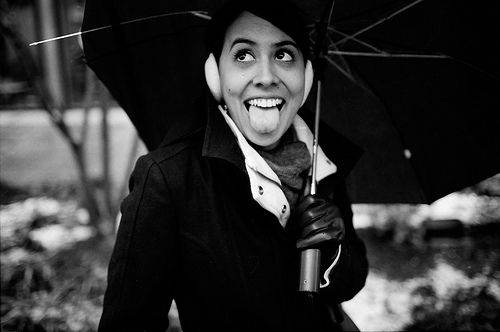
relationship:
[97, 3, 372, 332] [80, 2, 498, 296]
woman holding umbrella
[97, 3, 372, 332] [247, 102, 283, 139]
woman sticking out tongue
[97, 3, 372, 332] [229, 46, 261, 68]
woman has eye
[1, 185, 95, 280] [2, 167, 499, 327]
snow covering ground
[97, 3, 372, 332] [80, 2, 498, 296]
woman carrying umbrella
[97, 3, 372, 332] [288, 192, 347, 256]
woman wearing glove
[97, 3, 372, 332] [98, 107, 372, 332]
woman wearing jacket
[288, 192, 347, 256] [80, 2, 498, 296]
glove holding umbrella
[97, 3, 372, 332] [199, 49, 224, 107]
woman wearing muff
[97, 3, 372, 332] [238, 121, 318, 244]
woman wearing scarf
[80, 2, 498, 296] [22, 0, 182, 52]
umbrella has wire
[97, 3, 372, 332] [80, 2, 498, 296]
woman under umbrella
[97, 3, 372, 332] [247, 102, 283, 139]
woman has tongue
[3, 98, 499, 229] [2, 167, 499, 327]
pond next to ground